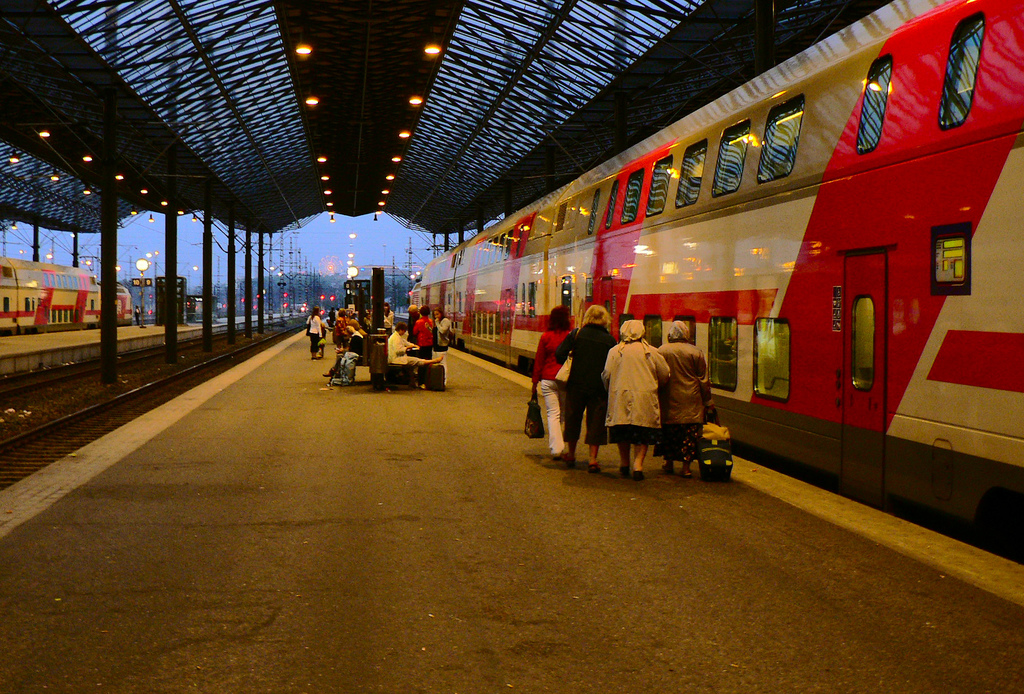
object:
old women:
[532, 305, 715, 482]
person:
[306, 305, 323, 359]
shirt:
[306, 314, 323, 337]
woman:
[555, 304, 618, 473]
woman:
[531, 305, 572, 461]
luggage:
[696, 422, 732, 481]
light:
[306, 97, 319, 104]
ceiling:
[276, 0, 463, 217]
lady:
[600, 319, 669, 480]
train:
[411, 0, 1024, 551]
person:
[388, 322, 443, 366]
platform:
[0, 310, 1024, 694]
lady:
[657, 320, 715, 477]